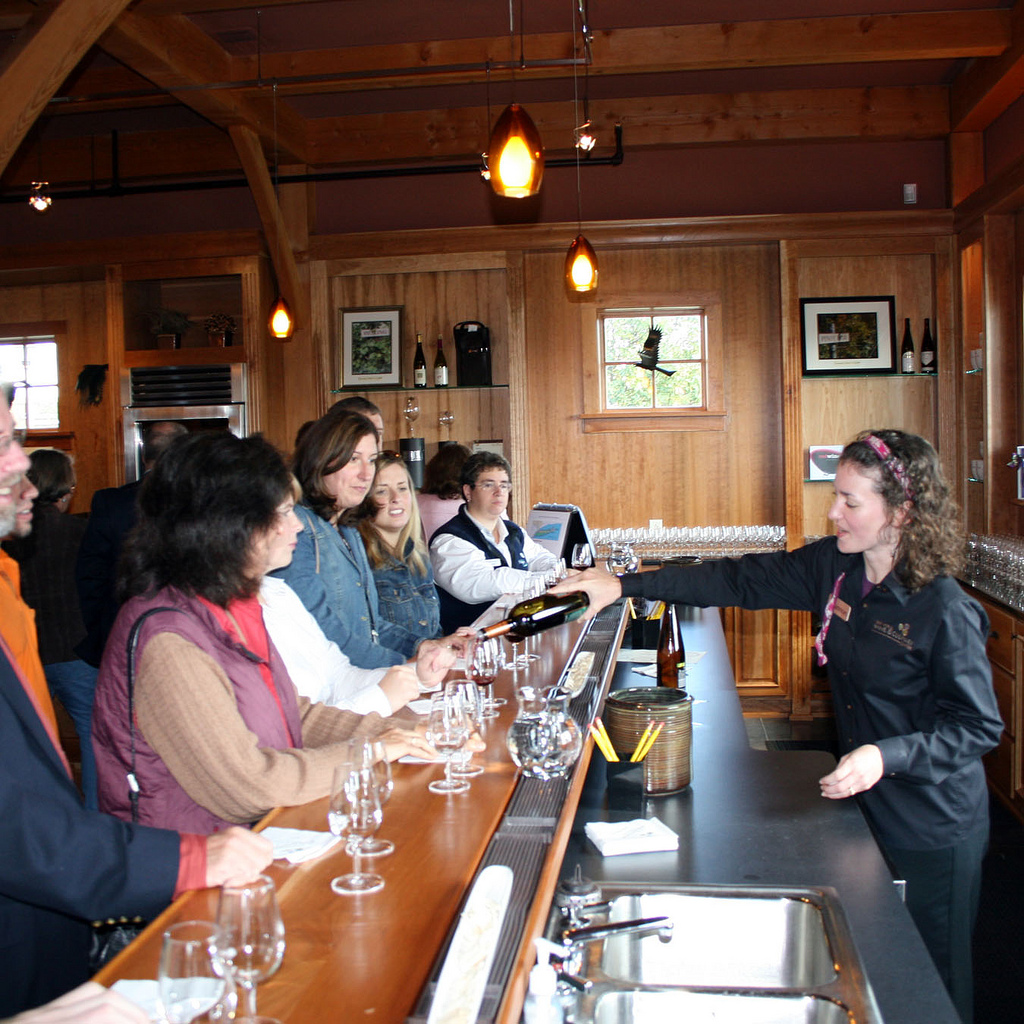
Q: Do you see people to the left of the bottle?
A: Yes, there is a person to the left of the bottle.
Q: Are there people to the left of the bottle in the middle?
A: Yes, there is a person to the left of the bottle.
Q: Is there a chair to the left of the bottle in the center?
A: No, there is a person to the left of the bottle.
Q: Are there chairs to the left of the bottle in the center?
A: No, there is a person to the left of the bottle.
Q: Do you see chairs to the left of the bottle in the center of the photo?
A: No, there is a person to the left of the bottle.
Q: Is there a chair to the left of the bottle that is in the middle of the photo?
A: No, there is a person to the left of the bottle.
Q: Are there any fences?
A: No, there are no fences.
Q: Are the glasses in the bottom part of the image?
A: Yes, the glasses are in the bottom of the image.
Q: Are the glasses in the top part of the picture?
A: No, the glasses are in the bottom of the image.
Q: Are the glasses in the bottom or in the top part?
A: The glasses are in the bottom of the image.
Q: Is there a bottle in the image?
A: Yes, there is a bottle.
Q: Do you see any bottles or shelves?
A: Yes, there is a bottle.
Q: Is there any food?
A: No, there is no food.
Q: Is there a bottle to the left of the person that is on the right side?
A: Yes, there is a bottle to the left of the person.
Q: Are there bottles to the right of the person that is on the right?
A: No, the bottle is to the left of the person.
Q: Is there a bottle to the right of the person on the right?
A: No, the bottle is to the left of the person.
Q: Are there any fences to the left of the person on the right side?
A: No, there is a bottle to the left of the person.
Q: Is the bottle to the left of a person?
A: Yes, the bottle is to the left of a person.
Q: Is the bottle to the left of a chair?
A: No, the bottle is to the left of a person.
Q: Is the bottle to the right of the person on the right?
A: No, the bottle is to the left of the person.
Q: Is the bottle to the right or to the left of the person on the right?
A: The bottle is to the left of the person.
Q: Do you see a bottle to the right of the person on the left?
A: Yes, there is a bottle to the right of the person.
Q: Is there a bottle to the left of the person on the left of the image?
A: No, the bottle is to the right of the person.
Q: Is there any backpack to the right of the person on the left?
A: No, there is a bottle to the right of the person.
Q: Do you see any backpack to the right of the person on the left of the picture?
A: No, there is a bottle to the right of the person.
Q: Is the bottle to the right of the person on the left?
A: Yes, the bottle is to the right of the person.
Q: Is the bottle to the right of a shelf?
A: No, the bottle is to the right of the person.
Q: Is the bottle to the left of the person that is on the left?
A: No, the bottle is to the right of the person.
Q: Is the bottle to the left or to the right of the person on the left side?
A: The bottle is to the right of the person.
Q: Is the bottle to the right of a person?
A: Yes, the bottle is to the right of a person.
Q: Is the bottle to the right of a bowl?
A: No, the bottle is to the right of a person.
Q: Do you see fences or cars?
A: No, there are no cars or fences.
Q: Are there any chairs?
A: No, there are no chairs.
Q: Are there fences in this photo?
A: No, there are no fences.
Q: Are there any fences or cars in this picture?
A: No, there are no fences or cars.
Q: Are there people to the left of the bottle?
A: Yes, there is a person to the left of the bottle.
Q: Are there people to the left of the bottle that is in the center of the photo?
A: Yes, there is a person to the left of the bottle.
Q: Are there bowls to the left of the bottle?
A: No, there is a person to the left of the bottle.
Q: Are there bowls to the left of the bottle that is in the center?
A: No, there is a person to the left of the bottle.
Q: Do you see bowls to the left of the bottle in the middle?
A: No, there is a person to the left of the bottle.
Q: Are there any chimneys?
A: No, there are no chimneys.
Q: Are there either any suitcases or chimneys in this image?
A: No, there are no chimneys or suitcases.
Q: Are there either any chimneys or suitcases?
A: No, there are no chimneys or suitcases.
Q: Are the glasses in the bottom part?
A: Yes, the glasses are in the bottom of the image.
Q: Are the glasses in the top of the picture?
A: No, the glasses are in the bottom of the image.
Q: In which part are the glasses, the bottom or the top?
A: The glasses are in the bottom of the image.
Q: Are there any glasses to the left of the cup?
A: Yes, there are glasses to the left of the cup.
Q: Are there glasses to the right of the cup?
A: No, the glasses are to the left of the cup.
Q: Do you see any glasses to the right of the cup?
A: No, the glasses are to the left of the cup.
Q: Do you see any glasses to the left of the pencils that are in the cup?
A: Yes, there are glasses to the left of the pencils.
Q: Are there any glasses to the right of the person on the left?
A: Yes, there are glasses to the right of the person.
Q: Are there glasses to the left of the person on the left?
A: No, the glasses are to the right of the person.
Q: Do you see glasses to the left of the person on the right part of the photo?
A: Yes, there are glasses to the left of the person.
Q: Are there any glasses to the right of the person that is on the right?
A: No, the glasses are to the left of the person.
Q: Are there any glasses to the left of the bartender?
A: Yes, there are glasses to the left of the bartender.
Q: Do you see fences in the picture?
A: No, there are no fences.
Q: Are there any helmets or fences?
A: No, there are no fences or helmets.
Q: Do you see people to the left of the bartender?
A: Yes, there is a person to the left of the bartender.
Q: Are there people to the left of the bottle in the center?
A: Yes, there is a person to the left of the bottle.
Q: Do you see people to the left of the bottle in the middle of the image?
A: Yes, there is a person to the left of the bottle.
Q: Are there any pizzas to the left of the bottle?
A: No, there is a person to the left of the bottle.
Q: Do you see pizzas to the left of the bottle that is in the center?
A: No, there is a person to the left of the bottle.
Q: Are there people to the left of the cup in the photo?
A: Yes, there is a person to the left of the cup.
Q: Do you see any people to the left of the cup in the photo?
A: Yes, there is a person to the left of the cup.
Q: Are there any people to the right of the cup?
A: No, the person is to the left of the cup.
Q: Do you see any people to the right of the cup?
A: No, the person is to the left of the cup.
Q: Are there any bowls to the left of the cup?
A: No, there is a person to the left of the cup.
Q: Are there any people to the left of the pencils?
A: Yes, there is a person to the left of the pencils.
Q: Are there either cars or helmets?
A: No, there are no cars or helmets.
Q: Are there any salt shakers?
A: No, there are no salt shakers.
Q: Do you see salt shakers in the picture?
A: No, there are no salt shakers.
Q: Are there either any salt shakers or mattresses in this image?
A: No, there are no salt shakers or mattresses.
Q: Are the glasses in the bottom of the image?
A: Yes, the glasses are in the bottom of the image.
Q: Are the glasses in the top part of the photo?
A: No, the glasses are in the bottom of the image.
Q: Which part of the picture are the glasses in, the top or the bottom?
A: The glasses are in the bottom of the image.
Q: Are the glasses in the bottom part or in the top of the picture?
A: The glasses are in the bottom of the image.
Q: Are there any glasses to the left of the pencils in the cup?
A: Yes, there are glasses to the left of the pencils.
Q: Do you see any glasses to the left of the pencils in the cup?
A: Yes, there are glasses to the left of the pencils.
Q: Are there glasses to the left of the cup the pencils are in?
A: Yes, there are glasses to the left of the cup.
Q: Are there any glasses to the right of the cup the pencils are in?
A: No, the glasses are to the left of the cup.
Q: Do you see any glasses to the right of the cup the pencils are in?
A: No, the glasses are to the left of the cup.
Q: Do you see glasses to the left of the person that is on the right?
A: Yes, there are glasses to the left of the person.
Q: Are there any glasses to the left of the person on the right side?
A: Yes, there are glasses to the left of the person.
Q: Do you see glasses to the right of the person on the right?
A: No, the glasses are to the left of the person.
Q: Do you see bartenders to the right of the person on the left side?
A: Yes, there is a bartender to the right of the person.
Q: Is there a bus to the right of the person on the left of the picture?
A: No, there is a bartender to the right of the person.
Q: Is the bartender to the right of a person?
A: Yes, the bartender is to the right of a person.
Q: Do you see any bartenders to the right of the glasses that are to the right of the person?
A: Yes, there is a bartender to the right of the glasses.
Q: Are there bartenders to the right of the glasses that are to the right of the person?
A: Yes, there is a bartender to the right of the glasses.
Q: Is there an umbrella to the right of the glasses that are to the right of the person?
A: No, there is a bartender to the right of the glasses.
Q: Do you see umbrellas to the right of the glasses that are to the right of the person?
A: No, there is a bartender to the right of the glasses.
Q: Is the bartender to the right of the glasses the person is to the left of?
A: Yes, the bartender is to the right of the glasses.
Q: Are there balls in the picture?
A: No, there are no balls.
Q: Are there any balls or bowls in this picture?
A: No, there are no balls or bowls.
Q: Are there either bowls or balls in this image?
A: No, there are no balls or bowls.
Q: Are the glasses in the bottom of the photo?
A: Yes, the glasses are in the bottom of the image.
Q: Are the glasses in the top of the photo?
A: No, the glasses are in the bottom of the image.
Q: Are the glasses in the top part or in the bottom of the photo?
A: The glasses are in the bottom of the image.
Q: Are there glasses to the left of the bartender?
A: Yes, there are glasses to the left of the bartender.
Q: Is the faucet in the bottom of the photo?
A: Yes, the faucet is in the bottom of the image.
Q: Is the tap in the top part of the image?
A: No, the tap is in the bottom of the image.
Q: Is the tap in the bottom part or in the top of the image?
A: The tap is in the bottom of the image.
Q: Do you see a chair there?
A: No, there are no chairs.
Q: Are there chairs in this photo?
A: No, there are no chairs.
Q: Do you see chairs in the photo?
A: No, there are no chairs.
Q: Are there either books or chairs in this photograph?
A: No, there are no chairs or books.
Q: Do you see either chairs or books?
A: No, there are no chairs or books.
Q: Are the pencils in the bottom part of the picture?
A: Yes, the pencils are in the bottom of the image.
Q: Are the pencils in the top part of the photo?
A: No, the pencils are in the bottom of the image.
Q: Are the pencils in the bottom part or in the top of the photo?
A: The pencils are in the bottom of the image.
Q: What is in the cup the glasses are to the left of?
A: The pencils are in the cup.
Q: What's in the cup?
A: The pencils are in the cup.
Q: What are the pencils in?
A: The pencils are in the cup.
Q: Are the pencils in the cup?
A: Yes, the pencils are in the cup.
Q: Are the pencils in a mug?
A: No, the pencils are in the cup.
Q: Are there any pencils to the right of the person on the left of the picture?
A: Yes, there are pencils to the right of the person.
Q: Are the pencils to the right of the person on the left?
A: Yes, the pencils are to the right of the person.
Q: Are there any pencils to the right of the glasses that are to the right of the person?
A: Yes, there are pencils to the right of the glasses.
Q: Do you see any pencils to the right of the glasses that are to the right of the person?
A: Yes, there are pencils to the right of the glasses.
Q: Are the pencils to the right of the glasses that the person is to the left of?
A: Yes, the pencils are to the right of the glasses.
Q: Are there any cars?
A: No, there are no cars.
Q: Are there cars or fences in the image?
A: No, there are no cars or fences.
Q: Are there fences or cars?
A: No, there are no cars or fences.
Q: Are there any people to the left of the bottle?
A: Yes, there is a person to the left of the bottle.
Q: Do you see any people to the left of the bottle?
A: Yes, there is a person to the left of the bottle.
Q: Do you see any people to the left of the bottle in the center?
A: Yes, there is a person to the left of the bottle.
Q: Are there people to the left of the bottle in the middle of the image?
A: Yes, there is a person to the left of the bottle.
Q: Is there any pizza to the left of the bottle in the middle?
A: No, there is a person to the left of the bottle.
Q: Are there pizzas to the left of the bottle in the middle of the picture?
A: No, there is a person to the left of the bottle.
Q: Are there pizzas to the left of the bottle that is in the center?
A: No, there is a person to the left of the bottle.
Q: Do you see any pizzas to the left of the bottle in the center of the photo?
A: No, there is a person to the left of the bottle.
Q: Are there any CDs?
A: No, there are no cds.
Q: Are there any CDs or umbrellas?
A: No, there are no CDs or umbrellas.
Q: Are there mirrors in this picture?
A: No, there are no mirrors.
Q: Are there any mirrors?
A: No, there are no mirrors.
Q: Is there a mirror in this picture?
A: No, there are no mirrors.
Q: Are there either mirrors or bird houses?
A: No, there are no mirrors or bird houses.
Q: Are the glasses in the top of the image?
A: No, the glasses are in the bottom of the image.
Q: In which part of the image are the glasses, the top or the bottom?
A: The glasses are in the bottom of the image.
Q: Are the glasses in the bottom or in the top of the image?
A: The glasses are in the bottom of the image.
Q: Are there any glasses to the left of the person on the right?
A: Yes, there are glasses to the left of the person.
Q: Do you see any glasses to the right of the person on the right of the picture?
A: No, the glasses are to the left of the person.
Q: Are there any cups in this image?
A: Yes, there is a cup.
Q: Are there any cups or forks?
A: Yes, there is a cup.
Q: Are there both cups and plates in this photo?
A: No, there is a cup but no plates.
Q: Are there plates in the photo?
A: No, there are no plates.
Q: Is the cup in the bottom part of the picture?
A: Yes, the cup is in the bottom of the image.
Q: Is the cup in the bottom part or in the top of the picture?
A: The cup is in the bottom of the image.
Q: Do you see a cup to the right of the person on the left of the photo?
A: Yes, there is a cup to the right of the person.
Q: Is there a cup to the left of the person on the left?
A: No, the cup is to the right of the person.